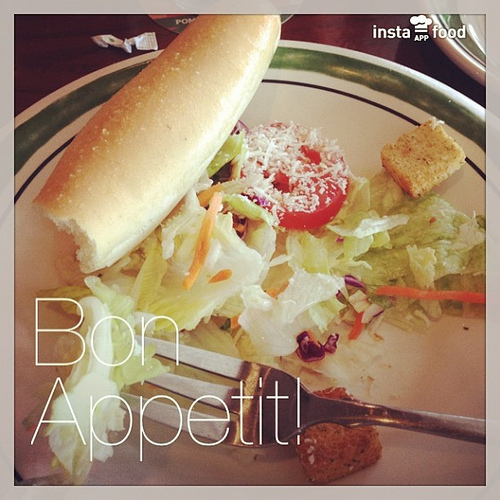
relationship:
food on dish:
[25, 33, 477, 475] [19, 29, 484, 490]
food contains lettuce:
[25, 33, 477, 475] [366, 211, 454, 272]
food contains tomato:
[25, 33, 477, 475] [242, 125, 352, 229]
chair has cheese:
[245, 126, 325, 163] [230, 109, 355, 219]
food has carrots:
[25, 33, 477, 475] [369, 282, 486, 307]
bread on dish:
[34, 25, 276, 286] [19, 29, 484, 490]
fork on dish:
[105, 324, 487, 491] [19, 29, 484, 490]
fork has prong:
[105, 324, 487, 491] [127, 344, 223, 427]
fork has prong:
[105, 324, 487, 491] [143, 362, 233, 405]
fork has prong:
[105, 324, 487, 491] [116, 399, 239, 455]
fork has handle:
[105, 324, 487, 491] [252, 363, 439, 451]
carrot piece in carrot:
[374, 285, 484, 306] [375, 281, 485, 309]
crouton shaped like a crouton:
[376, 121, 466, 198] [376, 121, 466, 198]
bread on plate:
[34, 14, 284, 273] [303, 30, 498, 185]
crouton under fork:
[293, 417, 390, 486] [124, 335, 390, 464]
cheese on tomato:
[241, 125, 346, 228] [242, 125, 352, 229]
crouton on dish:
[376, 121, 466, 198] [19, 29, 484, 490]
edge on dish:
[401, 67, 441, 87] [19, 29, 484, 490]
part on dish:
[410, 334, 472, 391] [19, 29, 484, 490]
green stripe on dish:
[12, 31, 482, 208] [19, 29, 484, 490]